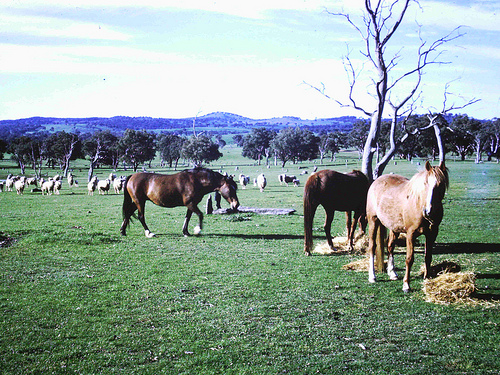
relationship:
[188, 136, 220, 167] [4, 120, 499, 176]
tree in grove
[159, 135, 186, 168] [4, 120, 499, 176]
tree in grove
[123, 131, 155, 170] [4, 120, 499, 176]
tree in grove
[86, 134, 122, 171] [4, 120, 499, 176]
tree in grove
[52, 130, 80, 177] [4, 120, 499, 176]
tree in grove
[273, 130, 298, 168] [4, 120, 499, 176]
tree in grove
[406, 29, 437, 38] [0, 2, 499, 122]
cloud in sky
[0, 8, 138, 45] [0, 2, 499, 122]
cloud in sky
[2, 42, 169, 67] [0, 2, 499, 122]
cloud in sky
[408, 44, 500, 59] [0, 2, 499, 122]
cloud in sky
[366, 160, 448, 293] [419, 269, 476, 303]
horse eats hay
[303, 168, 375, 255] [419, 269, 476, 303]
horse eats hay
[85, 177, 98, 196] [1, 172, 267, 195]
sheep in herd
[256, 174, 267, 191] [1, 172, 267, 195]
sheep in herd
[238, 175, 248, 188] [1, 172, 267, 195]
sheep in herd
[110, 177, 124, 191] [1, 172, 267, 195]
sheep in herd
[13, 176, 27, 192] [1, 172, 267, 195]
sheep in herd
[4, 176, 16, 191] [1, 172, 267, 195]
sheep in herd